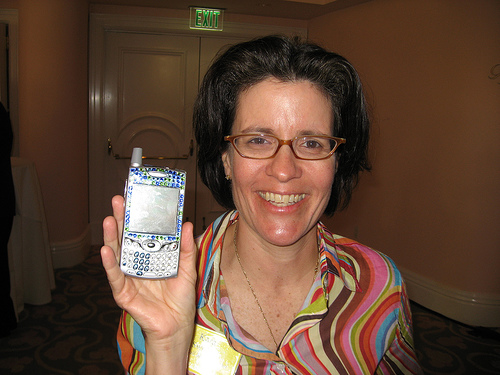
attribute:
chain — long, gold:
[227, 221, 282, 349]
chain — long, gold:
[308, 250, 318, 297]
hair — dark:
[190, 31, 372, 216]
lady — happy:
[89, 24, 416, 374]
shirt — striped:
[115, 207, 417, 372]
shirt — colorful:
[123, 219, 420, 370]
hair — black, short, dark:
[194, 36, 368, 223]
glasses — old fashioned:
[224, 127, 345, 160]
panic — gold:
[95, 122, 225, 317]